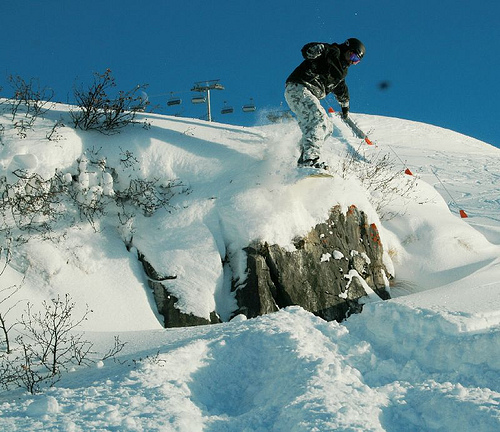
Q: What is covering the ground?
A: Snow.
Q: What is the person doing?
A: Snowboarding.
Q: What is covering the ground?
A: Snow.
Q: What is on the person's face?
A: Goggles.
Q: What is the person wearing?
A: Black jacket.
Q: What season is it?
A: Winter.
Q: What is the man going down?
A: A mountain.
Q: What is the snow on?
A: A rock.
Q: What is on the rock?
A: Snow.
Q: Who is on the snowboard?
A: A man.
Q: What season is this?
A: Winter.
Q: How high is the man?
A: Very High.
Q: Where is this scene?
A: Ski slope.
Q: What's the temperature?
A: 45.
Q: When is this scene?
A: Afternoon.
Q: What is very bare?
A: The bushes.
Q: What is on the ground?
A: Snow.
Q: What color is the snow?
A: White.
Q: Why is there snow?
A: Chilly weather.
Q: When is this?
A: Daytime.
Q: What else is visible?
A: Rocks.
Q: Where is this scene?
A: At a ski resort.